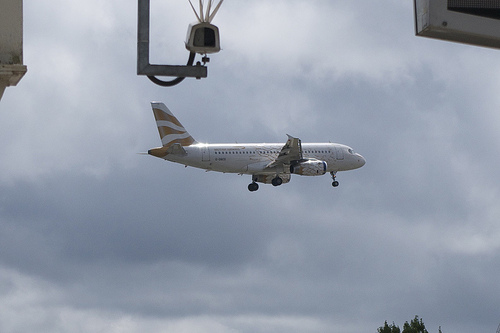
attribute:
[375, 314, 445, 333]
tree tops — leaf covered, green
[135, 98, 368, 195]
airplane — preparing to land, white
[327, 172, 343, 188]
landing gear — down, black, lowered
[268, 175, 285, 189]
landing gear — down, black, lowered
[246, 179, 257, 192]
landing gear — down, black, lowered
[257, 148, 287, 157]
window — row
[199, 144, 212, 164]
door — closed, white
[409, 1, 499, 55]
sign — metal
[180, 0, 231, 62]
equipment — small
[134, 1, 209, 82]
bracket — metal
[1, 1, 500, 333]
sky — grey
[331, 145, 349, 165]
door — white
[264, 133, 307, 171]
wing — large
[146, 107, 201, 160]
marking — gold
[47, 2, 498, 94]
clouds — white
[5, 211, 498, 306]
clouds — white